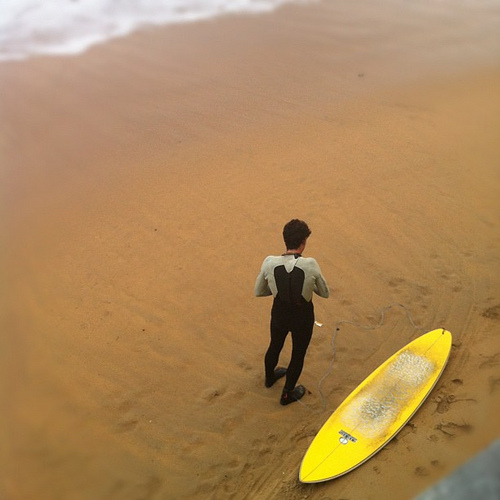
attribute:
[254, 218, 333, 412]
person — standing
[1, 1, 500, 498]
sand — wet, tan, smooth, here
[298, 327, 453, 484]
surfboard — yellow, worn out, waxed, brown, white, worn, used, pointy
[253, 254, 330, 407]
wetsuit — black, grey, white, gray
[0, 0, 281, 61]
water — coming, white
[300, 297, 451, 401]
cord — gray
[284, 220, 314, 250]
hair — short, brown, black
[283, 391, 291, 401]
spot — little, red